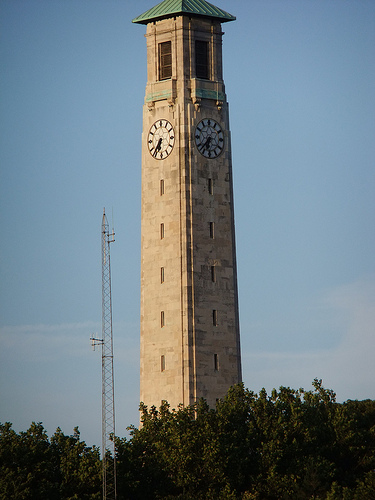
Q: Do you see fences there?
A: No, there are no fences.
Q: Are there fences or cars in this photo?
A: No, there are no fences or cars.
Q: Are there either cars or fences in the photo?
A: No, there are no fences or cars.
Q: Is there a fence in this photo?
A: No, there are no fences.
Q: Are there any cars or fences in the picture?
A: No, there are no fences or cars.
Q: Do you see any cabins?
A: No, there are no cabins.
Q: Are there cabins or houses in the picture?
A: No, there are no cabins or houses.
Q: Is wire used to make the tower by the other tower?
A: Yes, the tower is made of wire.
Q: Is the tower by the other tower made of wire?
A: Yes, the tower is made of wire.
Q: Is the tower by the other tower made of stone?
A: No, the tower is made of wire.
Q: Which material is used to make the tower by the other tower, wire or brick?
A: The tower is made of wire.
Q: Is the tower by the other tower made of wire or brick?
A: The tower is made of wire.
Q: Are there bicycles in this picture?
A: No, there are no bicycles.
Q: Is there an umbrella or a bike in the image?
A: No, there are no bikes or umbrellas.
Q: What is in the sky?
A: The clouds are in the sky.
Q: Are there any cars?
A: No, there are no cars.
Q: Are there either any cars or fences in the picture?
A: No, there are no cars or fences.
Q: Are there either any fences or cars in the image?
A: No, there are no cars or fences.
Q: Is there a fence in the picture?
A: No, there are no fences.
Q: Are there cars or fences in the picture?
A: No, there are no fences or cars.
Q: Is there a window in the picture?
A: Yes, there is a window.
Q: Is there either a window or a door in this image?
A: Yes, there is a window.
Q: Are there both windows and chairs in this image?
A: No, there is a window but no chairs.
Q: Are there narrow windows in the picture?
A: Yes, there is a narrow window.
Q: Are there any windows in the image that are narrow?
A: Yes, there is a window that is narrow.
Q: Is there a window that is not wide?
A: Yes, there is a narrow window.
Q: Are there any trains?
A: No, there are no trains.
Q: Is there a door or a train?
A: No, there are no trains or doors.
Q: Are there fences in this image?
A: No, there are no fences.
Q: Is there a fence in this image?
A: No, there are no fences.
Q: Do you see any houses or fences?
A: No, there are no fences or houses.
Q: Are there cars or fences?
A: No, there are no cars or fences.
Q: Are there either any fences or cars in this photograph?
A: No, there are no cars or fences.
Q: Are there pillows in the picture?
A: No, there are no pillows.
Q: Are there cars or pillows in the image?
A: No, there are no pillows or cars.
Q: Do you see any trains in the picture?
A: No, there are no trains.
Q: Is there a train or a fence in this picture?
A: No, there are no trains or fences.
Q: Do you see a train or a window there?
A: Yes, there is a window.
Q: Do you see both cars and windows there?
A: No, there is a window but no cars.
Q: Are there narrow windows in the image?
A: Yes, there is a narrow window.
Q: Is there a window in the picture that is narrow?
A: Yes, there is a window that is narrow.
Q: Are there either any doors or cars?
A: No, there are no cars or doors.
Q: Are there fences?
A: No, there are no fences.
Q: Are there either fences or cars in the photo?
A: No, there are no fences or cars.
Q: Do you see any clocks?
A: Yes, there is a clock.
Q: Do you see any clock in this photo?
A: Yes, there is a clock.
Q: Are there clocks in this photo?
A: Yes, there is a clock.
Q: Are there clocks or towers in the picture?
A: Yes, there is a clock.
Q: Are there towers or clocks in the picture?
A: Yes, there is a clock.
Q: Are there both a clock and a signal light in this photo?
A: No, there is a clock but no traffic lights.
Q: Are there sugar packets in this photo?
A: No, there are no sugar packets.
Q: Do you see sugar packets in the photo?
A: No, there are no sugar packets.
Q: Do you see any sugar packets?
A: No, there are no sugar packets.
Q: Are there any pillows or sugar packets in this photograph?
A: No, there are no sugar packets or pillows.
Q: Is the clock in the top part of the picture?
A: Yes, the clock is in the top of the image.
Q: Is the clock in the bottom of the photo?
A: No, the clock is in the top of the image.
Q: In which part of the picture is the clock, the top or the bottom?
A: The clock is in the top of the image.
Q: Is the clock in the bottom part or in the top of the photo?
A: The clock is in the top of the image.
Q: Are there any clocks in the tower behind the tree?
A: Yes, there is a clock in the tower.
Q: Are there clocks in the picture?
A: Yes, there is a clock.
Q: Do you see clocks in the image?
A: Yes, there is a clock.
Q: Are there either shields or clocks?
A: Yes, there is a clock.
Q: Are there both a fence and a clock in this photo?
A: No, there is a clock but no fences.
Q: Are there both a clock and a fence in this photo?
A: No, there is a clock but no fences.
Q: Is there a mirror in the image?
A: No, there are no mirrors.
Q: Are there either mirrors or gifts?
A: No, there are no mirrors or gifts.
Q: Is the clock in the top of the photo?
A: Yes, the clock is in the top of the image.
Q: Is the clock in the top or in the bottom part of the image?
A: The clock is in the top of the image.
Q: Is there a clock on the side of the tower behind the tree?
A: Yes, there is a clock on the side of the tower.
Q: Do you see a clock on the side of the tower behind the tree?
A: Yes, there is a clock on the side of the tower.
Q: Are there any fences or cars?
A: No, there are no cars or fences.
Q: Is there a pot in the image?
A: No, there are no pots.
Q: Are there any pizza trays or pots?
A: No, there are no pots or pizza trays.